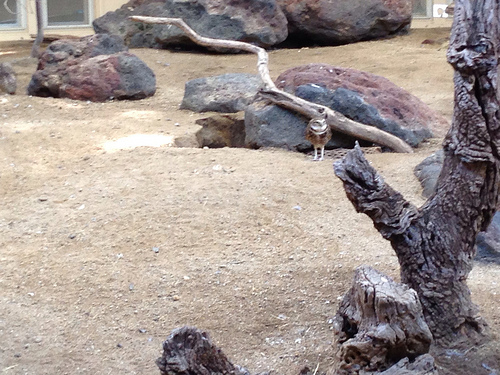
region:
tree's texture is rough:
[322, 154, 420, 301]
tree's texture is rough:
[390, 150, 452, 312]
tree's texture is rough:
[450, 136, 478, 258]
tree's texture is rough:
[326, 264, 435, 369]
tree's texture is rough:
[157, 327, 225, 371]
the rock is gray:
[240, 97, 334, 161]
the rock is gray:
[179, 63, 276, 110]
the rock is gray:
[97, 30, 167, 97]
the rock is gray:
[236, 94, 420, 179]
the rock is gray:
[177, 67, 247, 101]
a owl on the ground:
[303, 114, 331, 160]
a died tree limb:
[120, 11, 420, 148]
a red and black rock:
[34, 29, 152, 109]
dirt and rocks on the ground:
[115, 174, 299, 329]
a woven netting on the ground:
[317, 142, 375, 165]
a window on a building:
[40, 1, 93, 35]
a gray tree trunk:
[33, 1, 53, 58]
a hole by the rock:
[175, 109, 247, 151]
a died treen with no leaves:
[325, 1, 497, 372]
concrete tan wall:
[411, 19, 453, 29]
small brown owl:
[305, 113, 333, 159]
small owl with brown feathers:
[301, 113, 332, 159]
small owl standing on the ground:
[298, 110, 335, 168]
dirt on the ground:
[115, 142, 343, 239]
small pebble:
[30, 190, 56, 212]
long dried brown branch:
[122, 8, 417, 161]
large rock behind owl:
[235, 61, 435, 161]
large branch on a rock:
[125, 8, 419, 163]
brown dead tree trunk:
[329, 145, 499, 356]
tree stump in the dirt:
[335, 257, 427, 373]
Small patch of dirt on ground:
[43, 291, 76, 333]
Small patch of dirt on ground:
[83, 331, 137, 373]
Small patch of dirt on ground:
[199, 294, 269, 364]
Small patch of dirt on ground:
[278, 286, 328, 351]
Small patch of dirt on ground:
[205, 217, 285, 272]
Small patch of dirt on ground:
[106, 201, 178, 254]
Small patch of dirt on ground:
[14, 146, 106, 200]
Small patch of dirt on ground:
[129, 144, 179, 201]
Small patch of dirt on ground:
[206, 157, 332, 204]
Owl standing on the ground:
[283, 96, 354, 188]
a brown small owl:
[297, 107, 335, 167]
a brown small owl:
[289, 105, 359, 263]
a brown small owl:
[288, 100, 354, 170]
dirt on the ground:
[113, 164, 174, 271]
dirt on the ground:
[190, 200, 290, 300]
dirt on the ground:
[122, 199, 254, 271]